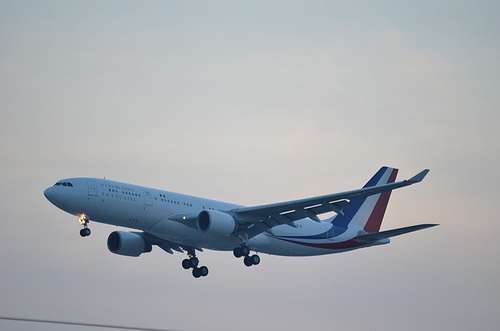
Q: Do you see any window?
A: Yes, there are windows.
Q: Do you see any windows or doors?
A: Yes, there are windows.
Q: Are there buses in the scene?
A: No, there are no buses.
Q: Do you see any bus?
A: No, there are no buses.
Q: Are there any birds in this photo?
A: No, there are no birds.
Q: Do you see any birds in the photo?
A: No, there are no birds.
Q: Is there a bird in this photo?
A: No, there are no birds.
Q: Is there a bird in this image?
A: No, there are no birds.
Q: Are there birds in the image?
A: No, there are no birds.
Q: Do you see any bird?
A: No, there are no birds.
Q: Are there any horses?
A: No, there are no horses.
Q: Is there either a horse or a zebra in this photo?
A: No, there are no horses or zebras.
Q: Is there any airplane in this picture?
A: Yes, there is an airplane.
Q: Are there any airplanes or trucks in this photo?
A: Yes, there is an airplane.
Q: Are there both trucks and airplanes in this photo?
A: No, there is an airplane but no trucks.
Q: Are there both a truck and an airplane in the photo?
A: No, there is an airplane but no trucks.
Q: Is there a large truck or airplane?
A: Yes, there is a large airplane.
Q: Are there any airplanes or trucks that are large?
A: Yes, the airplane is large.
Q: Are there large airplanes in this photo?
A: Yes, there is a large airplane.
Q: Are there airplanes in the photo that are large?
A: Yes, there is a large airplane.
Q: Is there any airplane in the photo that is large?
A: Yes, there is an airplane that is large.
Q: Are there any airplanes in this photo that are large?
A: Yes, there is an airplane that is large.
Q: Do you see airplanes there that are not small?
A: Yes, there is a large airplane.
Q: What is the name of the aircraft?
A: The aircraft is an airplane.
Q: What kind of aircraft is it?
A: The aircraft is an airplane.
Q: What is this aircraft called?
A: This is an airplane.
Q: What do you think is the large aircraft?
A: The aircraft is an airplane.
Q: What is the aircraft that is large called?
A: The aircraft is an airplane.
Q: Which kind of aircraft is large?
A: The aircraft is an airplane.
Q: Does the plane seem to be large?
A: Yes, the plane is large.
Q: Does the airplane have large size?
A: Yes, the airplane is large.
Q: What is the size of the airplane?
A: The airplane is large.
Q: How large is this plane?
A: The plane is large.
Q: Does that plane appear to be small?
A: No, the plane is large.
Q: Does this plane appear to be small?
A: No, the plane is large.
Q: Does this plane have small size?
A: No, the plane is large.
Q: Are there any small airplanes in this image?
A: No, there is an airplane but it is large.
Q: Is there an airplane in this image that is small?
A: No, there is an airplane but it is large.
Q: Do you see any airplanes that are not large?
A: No, there is an airplane but it is large.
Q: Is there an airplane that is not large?
A: No, there is an airplane but it is large.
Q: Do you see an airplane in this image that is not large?
A: No, there is an airplane but it is large.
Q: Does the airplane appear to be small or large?
A: The airplane is large.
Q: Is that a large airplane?
A: Yes, that is a large airplane.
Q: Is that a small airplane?
A: No, that is a large airplane.